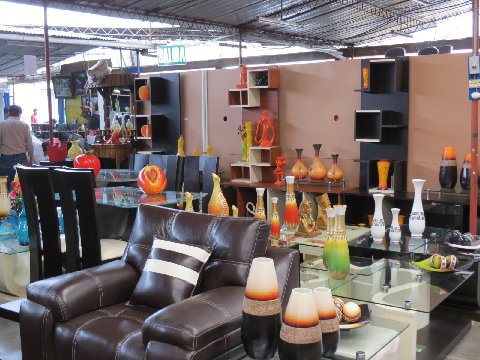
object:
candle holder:
[240, 257, 285, 360]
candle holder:
[277, 285, 325, 360]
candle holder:
[312, 283, 340, 357]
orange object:
[254, 109, 275, 147]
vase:
[327, 153, 344, 184]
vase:
[307, 143, 326, 181]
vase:
[290, 148, 309, 182]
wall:
[281, 62, 362, 183]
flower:
[137, 165, 168, 196]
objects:
[222, 126, 433, 344]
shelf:
[206, 51, 297, 197]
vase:
[322, 204, 350, 280]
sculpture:
[134, 163, 166, 195]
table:
[37, 175, 207, 237]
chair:
[18, 202, 302, 360]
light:
[4, 3, 173, 36]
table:
[110, 187, 478, 348]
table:
[93, 175, 207, 227]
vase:
[408, 179, 426, 236]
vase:
[438, 145, 457, 193]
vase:
[207, 172, 229, 218]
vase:
[246, 187, 267, 220]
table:
[226, 172, 378, 209]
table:
[49, 185, 204, 227]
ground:
[294, 79, 300, 133]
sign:
[156, 45, 187, 67]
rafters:
[6, 4, 476, 68]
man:
[1, 105, 36, 192]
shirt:
[0, 116, 35, 159]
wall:
[400, 87, 418, 140]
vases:
[371, 179, 427, 242]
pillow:
[123, 234, 213, 309]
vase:
[389, 207, 402, 242]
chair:
[13, 164, 101, 288]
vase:
[370, 194, 387, 241]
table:
[348, 221, 478, 270]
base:
[375, 279, 454, 332]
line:
[142, 258, 199, 286]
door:
[352, 58, 410, 195]